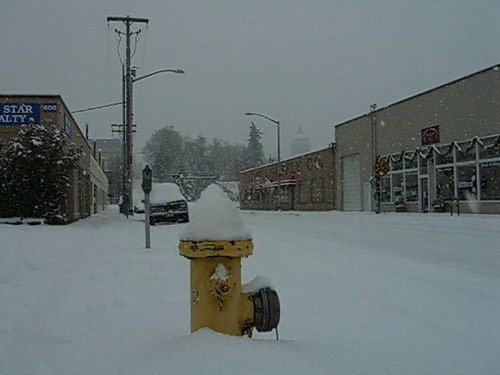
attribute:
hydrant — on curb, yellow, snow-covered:
[156, 223, 300, 356]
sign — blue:
[1, 87, 54, 129]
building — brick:
[220, 161, 337, 207]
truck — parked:
[137, 177, 189, 225]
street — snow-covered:
[245, 220, 450, 347]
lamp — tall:
[157, 62, 190, 80]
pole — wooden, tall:
[129, 52, 147, 223]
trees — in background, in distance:
[145, 98, 272, 202]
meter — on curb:
[135, 162, 179, 237]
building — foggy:
[9, 103, 114, 228]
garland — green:
[382, 130, 497, 163]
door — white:
[345, 136, 380, 223]